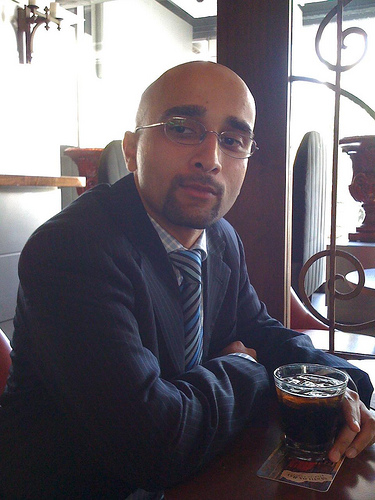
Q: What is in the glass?
A: A dark liquid.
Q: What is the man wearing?
A: A suit jacket.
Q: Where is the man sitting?
A: Inside a bar.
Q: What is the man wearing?
A: A blue suit and tie.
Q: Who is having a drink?
A: The business man.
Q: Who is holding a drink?
A: A man.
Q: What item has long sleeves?
A: A jacket.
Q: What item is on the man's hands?
A: A drink.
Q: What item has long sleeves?
A: A jacket.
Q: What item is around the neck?
A: A tie.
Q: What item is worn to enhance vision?
A: Glasses.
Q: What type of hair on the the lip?
A: Moustache.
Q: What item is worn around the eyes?
A: Glasses.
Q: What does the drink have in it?
A: Ice.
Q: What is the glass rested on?
A: A coaster.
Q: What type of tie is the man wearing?
A: Stripe.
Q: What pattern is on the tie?
A: Stripes.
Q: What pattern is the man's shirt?
A: Plaid.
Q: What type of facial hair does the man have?
A: A mustache and beard.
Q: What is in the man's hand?
A: A drink.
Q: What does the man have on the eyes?
A: Glasses.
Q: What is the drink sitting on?
A: A coaster.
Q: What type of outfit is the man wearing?
A: A suit.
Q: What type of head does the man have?
A: Bald.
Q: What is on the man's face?
A: Glasses.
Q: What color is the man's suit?
A: Black.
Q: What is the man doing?
A: Drinking a beverage.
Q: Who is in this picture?
A: A man.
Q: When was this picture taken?
A: Daytime.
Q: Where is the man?
A: A restaurant.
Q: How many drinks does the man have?
A: One.